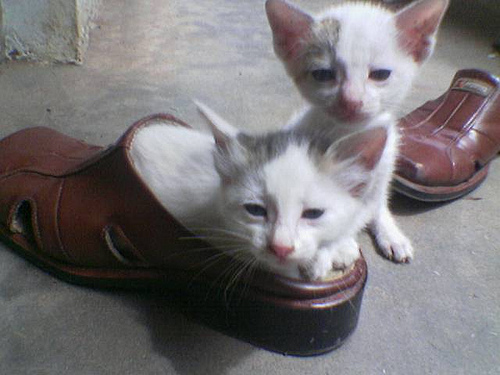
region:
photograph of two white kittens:
[26, 10, 485, 372]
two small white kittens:
[172, 20, 436, 285]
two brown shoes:
[57, 43, 499, 340]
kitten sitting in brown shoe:
[10, 101, 369, 305]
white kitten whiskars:
[174, 222, 268, 310]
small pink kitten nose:
[260, 229, 302, 266]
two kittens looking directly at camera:
[207, 17, 432, 312]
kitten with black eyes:
[222, 193, 339, 230]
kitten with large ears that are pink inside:
[260, 1, 448, 64]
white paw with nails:
[372, 232, 426, 275]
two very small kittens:
[128, 1, 451, 309]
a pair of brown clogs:
[0, 67, 498, 356]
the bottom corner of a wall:
[1, 1, 98, 63]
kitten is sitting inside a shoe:
[0, 97, 388, 357]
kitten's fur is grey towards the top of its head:
[211, 130, 333, 188]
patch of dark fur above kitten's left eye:
[302, 17, 340, 88]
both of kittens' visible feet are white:
[302, 225, 412, 282]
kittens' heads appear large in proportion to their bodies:
[129, 1, 449, 281]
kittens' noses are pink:
[268, 92, 363, 259]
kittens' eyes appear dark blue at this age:
[240, 65, 390, 221]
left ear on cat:
[391, 0, 462, 60]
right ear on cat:
[257, 5, 320, 50]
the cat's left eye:
[360, 62, 397, 90]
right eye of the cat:
[301, 63, 339, 83]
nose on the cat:
[342, 75, 367, 109]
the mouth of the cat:
[340, 110, 373, 125]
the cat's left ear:
[325, 116, 387, 197]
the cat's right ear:
[188, 97, 243, 159]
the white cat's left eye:
[297, 197, 332, 227]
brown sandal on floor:
[2, 105, 375, 373]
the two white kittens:
[130, 0, 449, 318]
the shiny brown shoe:
[391, 69, 498, 201]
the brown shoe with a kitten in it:
[0, 113, 366, 356]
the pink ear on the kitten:
[265, 0, 315, 63]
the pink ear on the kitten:
[392, 0, 447, 67]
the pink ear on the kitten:
[322, 125, 387, 198]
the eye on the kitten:
[240, 201, 267, 217]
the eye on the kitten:
[300, 208, 325, 219]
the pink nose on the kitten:
[267, 243, 293, 258]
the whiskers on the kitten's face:
[168, 218, 367, 315]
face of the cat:
[266, 20, 418, 120]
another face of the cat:
[223, 160, 352, 282]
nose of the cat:
[256, 212, 310, 270]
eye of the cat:
[291, 190, 340, 236]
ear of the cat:
[323, 118, 400, 180]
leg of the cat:
[376, 223, 434, 268]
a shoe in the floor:
[18, 144, 303, 339]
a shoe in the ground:
[21, 145, 209, 282]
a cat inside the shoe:
[88, 120, 467, 357]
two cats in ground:
[161, 20, 471, 334]